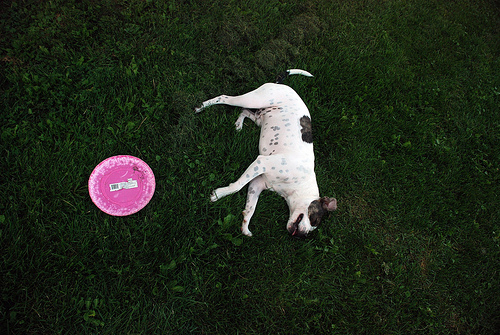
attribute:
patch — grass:
[53, 33, 155, 107]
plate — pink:
[88, 152, 155, 217]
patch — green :
[383, 113, 440, 165]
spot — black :
[261, 145, 266, 152]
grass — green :
[334, 76, 484, 313]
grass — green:
[192, 241, 282, 334]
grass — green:
[338, 109, 487, 285]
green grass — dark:
[366, 90, 437, 169]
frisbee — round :
[87, 153, 157, 215]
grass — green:
[368, 104, 471, 228]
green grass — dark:
[42, 34, 147, 118]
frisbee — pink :
[87, 156, 166, 225]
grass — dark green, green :
[2, 4, 498, 333]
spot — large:
[300, 114, 316, 144]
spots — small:
[273, 124, 281, 152]